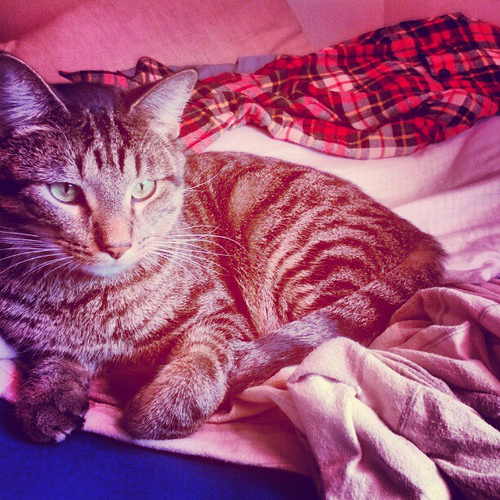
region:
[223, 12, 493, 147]
blanket with pattern on the couch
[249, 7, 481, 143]
blanket with plaid pattern on the couch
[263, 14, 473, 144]
blanket that is red, blue, and white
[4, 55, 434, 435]
a cat relaxing on the blanket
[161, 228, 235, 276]
a cat's white whiskers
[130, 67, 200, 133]
a cat's left pointy ear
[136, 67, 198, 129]
a cat's left ear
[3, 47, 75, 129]
a cat's right pointy ear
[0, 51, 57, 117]
a cat's right ear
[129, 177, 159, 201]
a cat's hazel eyes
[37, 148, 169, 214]
green eyes of cat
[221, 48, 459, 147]
flannel blanket with red and black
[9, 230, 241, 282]
white whiskers of cat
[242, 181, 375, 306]
pattern on cats fur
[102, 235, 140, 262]
pink nose of cat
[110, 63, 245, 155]
ear standing straight up on cat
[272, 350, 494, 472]
blanket cat is laying on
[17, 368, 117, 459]
paw of cat laying down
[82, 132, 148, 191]
pattern on cats head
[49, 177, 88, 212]
wide green eye of cat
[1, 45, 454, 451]
A brown tabby cat lounging on blankets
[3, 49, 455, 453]
A brown tabby cat on blankets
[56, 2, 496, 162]
the shirt is plaid patterned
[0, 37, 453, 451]
cat is laying down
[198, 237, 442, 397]
cat's tail is curled around it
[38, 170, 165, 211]
cat's eyes are green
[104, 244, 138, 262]
cat's nose is pink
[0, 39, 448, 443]
cat is gray and black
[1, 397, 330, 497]
the blanket is blue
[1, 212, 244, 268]
cat's whiskers are white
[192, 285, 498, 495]
blanket under the cat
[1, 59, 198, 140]
fur in cat's ears